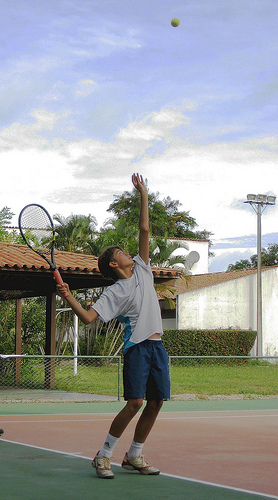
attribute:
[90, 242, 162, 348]
shirt — short sleeve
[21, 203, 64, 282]
tennis racket — black , orange 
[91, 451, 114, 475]
shoe — white , red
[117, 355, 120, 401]
pole — green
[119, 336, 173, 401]
shorts — blue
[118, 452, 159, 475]
shoe — red and white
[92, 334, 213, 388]
shorts — blue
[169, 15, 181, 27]
ball — green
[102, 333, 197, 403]
shorts — blue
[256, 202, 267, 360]
pole — gray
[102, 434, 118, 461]
sock — tall, white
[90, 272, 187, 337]
shirt — white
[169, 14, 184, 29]
ball — aired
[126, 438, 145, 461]
sock — tall, white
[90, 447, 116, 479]
shoe — red and white